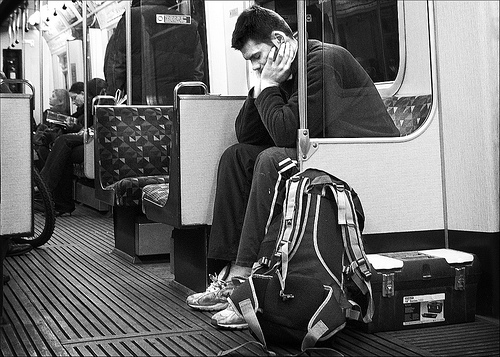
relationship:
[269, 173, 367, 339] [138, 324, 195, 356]
bag on floor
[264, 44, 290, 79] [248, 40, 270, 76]
hand on face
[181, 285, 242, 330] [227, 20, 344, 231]
feet below man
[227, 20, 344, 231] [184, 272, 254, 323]
man has shoe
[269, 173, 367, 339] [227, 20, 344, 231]
bag next to man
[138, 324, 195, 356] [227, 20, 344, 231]
floor below man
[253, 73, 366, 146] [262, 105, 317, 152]
shirt has sleeve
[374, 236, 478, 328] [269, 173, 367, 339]
case next to bag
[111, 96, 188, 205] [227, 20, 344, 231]
seat next to man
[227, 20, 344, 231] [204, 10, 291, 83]
man has head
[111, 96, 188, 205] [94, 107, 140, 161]
seat has back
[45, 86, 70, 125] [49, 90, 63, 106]
woman has head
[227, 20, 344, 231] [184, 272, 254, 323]
man wearing shoe